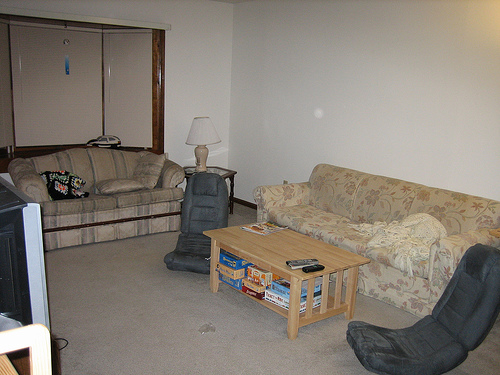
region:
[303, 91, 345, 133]
small dent in the white wall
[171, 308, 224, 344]
small water spot on floor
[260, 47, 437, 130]
white paint on the wall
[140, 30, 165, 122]
brown frame on the wall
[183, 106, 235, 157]
white lamp shade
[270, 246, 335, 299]
remotes on the brown table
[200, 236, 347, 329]
games under the brown table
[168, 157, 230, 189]
glass on brown table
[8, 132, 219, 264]
tan and blue sofa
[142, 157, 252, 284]
black seat on the floor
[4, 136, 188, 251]
a tan striped couch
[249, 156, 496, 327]
a tan flowered couch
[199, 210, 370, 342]
a blonde wood coffee table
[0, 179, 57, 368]
a flat screen television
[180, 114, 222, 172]
a beige table lamp with white shade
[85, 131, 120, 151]
a white toy car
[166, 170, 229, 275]
a grey floor gaming chair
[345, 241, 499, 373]
a grey floor gaming chair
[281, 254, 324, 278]
a set of remote controls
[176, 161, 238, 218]
a wood and glass end table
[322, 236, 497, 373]
Chair on the floor on right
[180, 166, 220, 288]
Chair on the floor on left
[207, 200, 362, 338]
wooden table in front of couch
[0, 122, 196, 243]
couch on the left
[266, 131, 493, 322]
couch on the right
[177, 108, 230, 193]
lamp on the side table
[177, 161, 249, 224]
wooden small table between couches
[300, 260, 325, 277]
tv remote on the table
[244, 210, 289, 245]
magazine on the table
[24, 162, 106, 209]
blanket on couch on left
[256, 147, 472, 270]
the couch with floral prints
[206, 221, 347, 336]
the coffee table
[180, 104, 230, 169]
lamp on the table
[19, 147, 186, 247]
the couch by the window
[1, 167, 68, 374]
the side of the tv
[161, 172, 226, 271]
the black chair by the coffee table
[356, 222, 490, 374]
the black chair nearest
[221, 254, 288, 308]
the bunch of board games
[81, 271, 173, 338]
the carpet in front of the table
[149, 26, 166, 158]
the side of the window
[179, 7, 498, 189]
The wall is white.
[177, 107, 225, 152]
The lamp shade is white.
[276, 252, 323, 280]
remotes on the table.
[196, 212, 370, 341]
The table is brown.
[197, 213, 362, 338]
the table is wooden.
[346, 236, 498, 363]
The chair is black.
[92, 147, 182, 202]
Pillows on the couch.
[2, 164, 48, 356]
TV is black and silver.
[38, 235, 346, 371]
The carpet is grey.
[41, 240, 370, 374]
The ground is carpet.